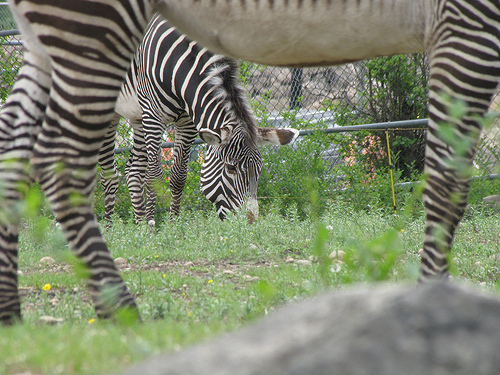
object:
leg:
[416, 0, 499, 282]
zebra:
[0, 0, 500, 326]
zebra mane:
[203, 57, 257, 148]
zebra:
[96, 13, 300, 234]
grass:
[0, 203, 500, 375]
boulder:
[131, 279, 499, 375]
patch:
[146, 241, 343, 288]